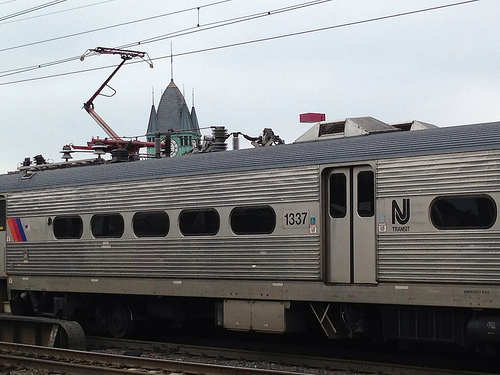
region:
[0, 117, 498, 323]
this is a train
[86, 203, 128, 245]
a window of a train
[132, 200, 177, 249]
a window of a train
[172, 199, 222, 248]
a window of a train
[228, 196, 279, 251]
a window of a train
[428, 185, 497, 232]
a window of a train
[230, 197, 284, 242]
the window is oval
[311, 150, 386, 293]
the door is closed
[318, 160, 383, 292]
the door is silver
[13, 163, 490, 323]
the train is silver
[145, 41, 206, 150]
the church roof is grey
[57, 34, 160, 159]
the equipment is red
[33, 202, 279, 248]
windows on a train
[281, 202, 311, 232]
numbers on a train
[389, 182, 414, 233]
a black logo on a train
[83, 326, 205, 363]
a track next to the train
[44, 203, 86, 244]
small window on train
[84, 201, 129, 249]
small window on train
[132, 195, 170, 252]
small window on train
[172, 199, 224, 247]
small window on train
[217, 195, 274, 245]
small window on train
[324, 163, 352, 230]
small window on train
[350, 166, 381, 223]
small window on train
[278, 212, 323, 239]
black numbers on train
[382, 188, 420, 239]
black letter on train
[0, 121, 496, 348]
the train is silver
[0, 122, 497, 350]
the windows on the train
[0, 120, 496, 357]
the door on the train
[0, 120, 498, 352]
the blue on the train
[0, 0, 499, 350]
the wires above the train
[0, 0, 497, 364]
the sky above the train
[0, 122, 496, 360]
the numbers on the train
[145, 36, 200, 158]
the tall green tower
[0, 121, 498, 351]
the numbers 1337 on the train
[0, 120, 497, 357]
the orange color on the train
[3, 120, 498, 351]
this is a train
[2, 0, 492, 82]
these are power lines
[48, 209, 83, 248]
a window on the train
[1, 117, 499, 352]
Train car over railroad tracks.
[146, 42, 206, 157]
Green clock tower in the distance.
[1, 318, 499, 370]
Railroad tracks with train riding on it.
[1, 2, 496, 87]
Electric cables connecting to a train.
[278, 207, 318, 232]
number 1337 in black on train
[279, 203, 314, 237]
numbers in black on silver train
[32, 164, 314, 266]
row of tinted windows on side of train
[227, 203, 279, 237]
tinted window on side of train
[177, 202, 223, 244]
tinted window on side of train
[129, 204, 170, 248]
tinted window on side of train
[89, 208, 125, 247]
tinted window on side of train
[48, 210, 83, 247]
tinted window on side of train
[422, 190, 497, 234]
tinted window on side of train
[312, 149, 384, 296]
sliding doors on silver train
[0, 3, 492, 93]
electrical train power wires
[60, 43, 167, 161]
train power contact arm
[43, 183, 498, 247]
row of windows on train car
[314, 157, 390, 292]
silver double door on train car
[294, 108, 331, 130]
red box atop train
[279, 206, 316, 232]
black train identification number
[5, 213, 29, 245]
colorful stripes on side of train car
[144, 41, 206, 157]
aqua blue clock tower behind train car